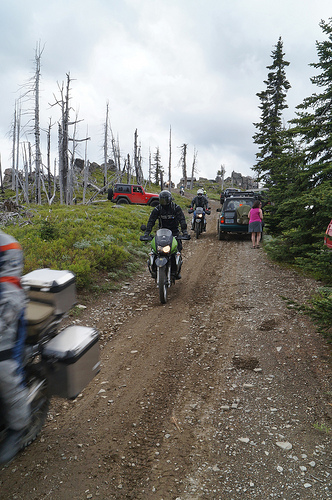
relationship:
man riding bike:
[142, 189, 190, 251] [135, 192, 194, 305]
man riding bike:
[142, 189, 190, 280] [187, 177, 219, 247]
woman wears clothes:
[248, 201, 264, 249] [252, 203, 263, 235]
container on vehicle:
[19, 265, 83, 313] [1, 267, 102, 462]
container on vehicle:
[40, 322, 110, 401] [1, 267, 102, 462]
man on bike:
[190, 188, 209, 232] [187, 206, 208, 237]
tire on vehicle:
[235, 205, 252, 229] [219, 193, 241, 225]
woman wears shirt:
[246, 200, 265, 251] [248, 207, 261, 221]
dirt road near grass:
[0, 189, 332, 500] [1, 163, 187, 298]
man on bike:
[142, 189, 190, 280] [139, 224, 191, 303]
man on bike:
[142, 189, 190, 280] [134, 225, 189, 309]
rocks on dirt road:
[243, 378, 281, 414] [0, 189, 332, 500]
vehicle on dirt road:
[216, 188, 264, 240] [33, 189, 329, 498]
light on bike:
[194, 212, 204, 220] [189, 204, 209, 236]